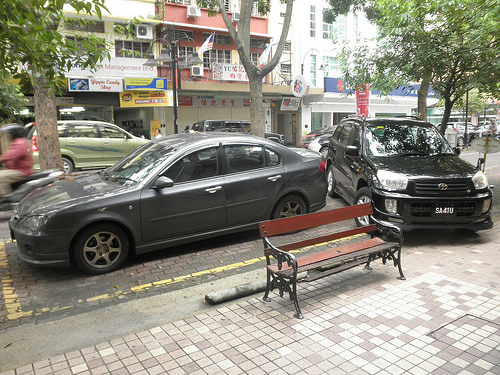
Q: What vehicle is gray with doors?
A: A car.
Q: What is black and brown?
A: The bench.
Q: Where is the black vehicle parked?
A: At the curb.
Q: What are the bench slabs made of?
A: Wood.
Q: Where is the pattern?
A: On the cobblestones.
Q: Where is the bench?
A: Beside the road.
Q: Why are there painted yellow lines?
A: To indicate parking place.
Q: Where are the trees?
A: Behind the parked cars.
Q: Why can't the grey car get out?
A: Black car parked behind it.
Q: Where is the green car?
A: On the street.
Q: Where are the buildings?
A: Behind the cars, trees and road.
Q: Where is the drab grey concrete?
A: Between the bench and grey car.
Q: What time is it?
A: Afternoon.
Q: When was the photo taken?
A: During the daytime.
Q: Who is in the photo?
A: No people.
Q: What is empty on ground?
A: The bench.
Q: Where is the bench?
A: On ground.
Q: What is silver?
A: The car.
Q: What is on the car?
A: Tires.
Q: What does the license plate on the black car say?
A: SA4IU.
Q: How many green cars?
A: One.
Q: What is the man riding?
A: Motorscooter.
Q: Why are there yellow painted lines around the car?
A: Marks the parking place.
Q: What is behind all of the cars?
A: A row of buildings.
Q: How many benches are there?
A: One.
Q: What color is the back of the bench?
A: Red.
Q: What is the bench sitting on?
A: Tile.